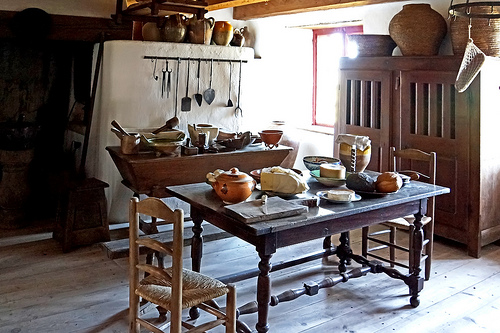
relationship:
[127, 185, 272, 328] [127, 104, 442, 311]
chair under table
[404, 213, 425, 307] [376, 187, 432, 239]
wood leg on table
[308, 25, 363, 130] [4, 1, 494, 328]
window in kitchen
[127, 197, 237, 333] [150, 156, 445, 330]
chair under table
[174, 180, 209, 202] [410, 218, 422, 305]
table has wood leg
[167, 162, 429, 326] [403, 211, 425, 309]
table has leg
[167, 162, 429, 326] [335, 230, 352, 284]
table has leg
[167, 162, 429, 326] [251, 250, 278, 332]
table has leg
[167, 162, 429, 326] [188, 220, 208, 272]
table has leg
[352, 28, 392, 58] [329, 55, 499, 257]
basket on cabinet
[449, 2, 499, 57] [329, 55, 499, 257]
basket on cabinet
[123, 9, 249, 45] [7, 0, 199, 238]
jars are on top of wall